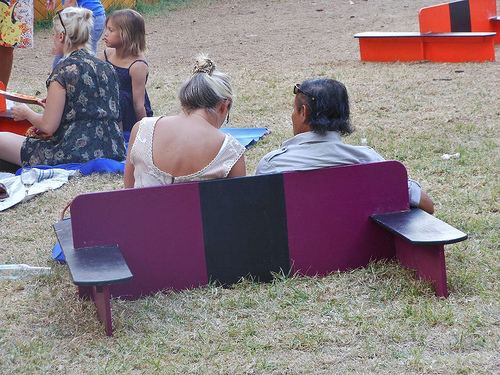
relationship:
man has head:
[234, 70, 430, 205] [261, 66, 373, 157]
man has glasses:
[234, 70, 430, 205] [286, 69, 347, 129]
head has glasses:
[261, 66, 373, 157] [286, 69, 347, 129]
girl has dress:
[92, 3, 154, 137] [99, 48, 151, 130]